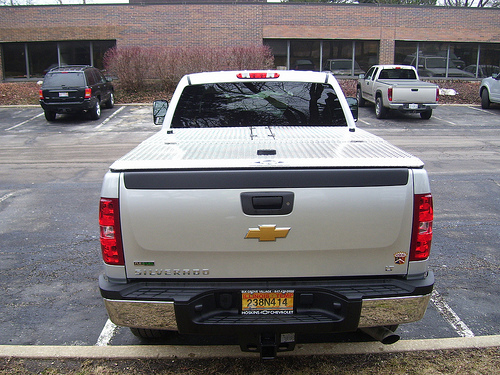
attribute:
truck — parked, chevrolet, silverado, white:
[97, 71, 436, 365]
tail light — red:
[99, 197, 125, 265]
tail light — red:
[408, 192, 433, 262]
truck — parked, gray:
[354, 63, 441, 121]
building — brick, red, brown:
[2, 2, 500, 83]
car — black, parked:
[38, 63, 115, 122]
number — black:
[247, 298, 289, 308]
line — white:
[94, 315, 119, 347]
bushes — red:
[102, 46, 274, 93]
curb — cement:
[0, 336, 498, 357]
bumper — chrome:
[97, 275, 434, 329]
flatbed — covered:
[98, 129, 436, 282]